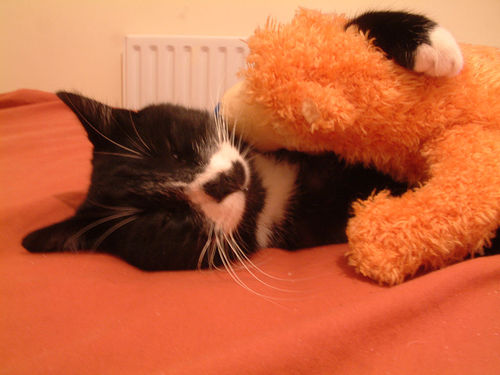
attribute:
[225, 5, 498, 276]
brown toy — stuffed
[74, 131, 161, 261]
eyelashes — white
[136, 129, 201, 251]
eyes — closed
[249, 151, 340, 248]
chest — white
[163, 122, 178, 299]
cats eyes — closed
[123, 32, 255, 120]
a/c — white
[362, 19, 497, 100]
leg — black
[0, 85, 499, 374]
blanket — sand colored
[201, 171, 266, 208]
nose — black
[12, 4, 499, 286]
cat — white patch on face, white, black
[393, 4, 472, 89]
paw — white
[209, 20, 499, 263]
animal — orange, stuffed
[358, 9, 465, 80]
paw — white, black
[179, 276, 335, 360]
blanket — pink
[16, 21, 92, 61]
walls — white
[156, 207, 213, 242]
eyes — shut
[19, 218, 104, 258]
ear — black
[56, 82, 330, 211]
cat — black, white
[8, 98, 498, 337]
red sheet — LIGHT RED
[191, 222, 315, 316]
whiskers — white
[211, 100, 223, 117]
nose — blue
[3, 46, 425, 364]
cat — white, black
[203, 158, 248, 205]
nose — black 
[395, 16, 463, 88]
paw — white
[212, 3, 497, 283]
teddy bear — orange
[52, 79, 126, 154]
ear — black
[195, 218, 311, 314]
whiskers — white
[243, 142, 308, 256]
markings — white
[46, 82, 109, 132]
ears — black 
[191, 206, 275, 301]
whiskers — white